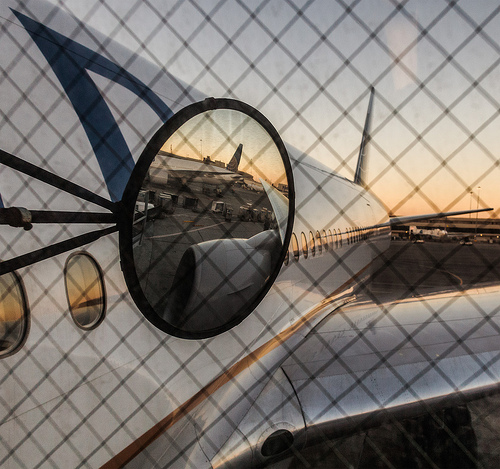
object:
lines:
[414, 247, 499, 293]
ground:
[380, 240, 497, 289]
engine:
[163, 226, 281, 331]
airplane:
[407, 225, 452, 245]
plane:
[14, 17, 489, 467]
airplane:
[0, 0, 497, 465]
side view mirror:
[117, 93, 294, 341]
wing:
[221, 279, 499, 456]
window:
[61, 249, 112, 329]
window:
[288, 231, 301, 263]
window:
[300, 231, 310, 261]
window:
[309, 230, 317, 258]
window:
[315, 231, 324, 253]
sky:
[179, 0, 499, 106]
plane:
[142, 141, 251, 189]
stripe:
[90, 298, 360, 469]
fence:
[1, 0, 500, 469]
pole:
[0, 139, 121, 210]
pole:
[0, 203, 121, 230]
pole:
[0, 225, 131, 275]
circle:
[260, 428, 295, 457]